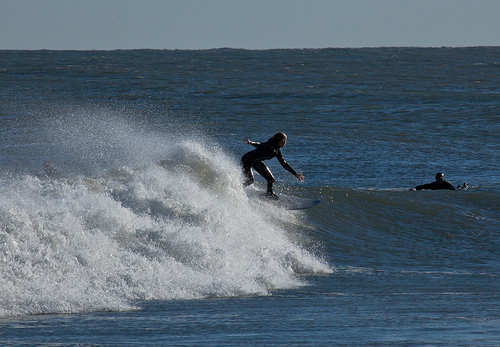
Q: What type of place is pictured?
A: It is an ocean.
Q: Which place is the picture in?
A: It is at the ocean.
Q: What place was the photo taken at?
A: It was taken at the ocean.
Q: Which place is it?
A: It is an ocean.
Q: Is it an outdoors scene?
A: Yes, it is outdoors.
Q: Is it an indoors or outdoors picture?
A: It is outdoors.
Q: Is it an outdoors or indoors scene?
A: It is outdoors.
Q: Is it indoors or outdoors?
A: It is outdoors.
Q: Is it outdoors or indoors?
A: It is outdoors.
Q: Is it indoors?
A: No, it is outdoors.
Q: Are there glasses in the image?
A: No, there are no glasses.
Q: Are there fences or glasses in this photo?
A: No, there are no glasses or fences.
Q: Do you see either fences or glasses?
A: No, there are no glasses or fences.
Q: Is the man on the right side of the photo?
A: Yes, the man is on the right of the image.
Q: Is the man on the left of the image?
A: No, the man is on the right of the image.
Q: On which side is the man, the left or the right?
A: The man is on the right of the image.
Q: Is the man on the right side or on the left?
A: The man is on the right of the image.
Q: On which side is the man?
A: The man is on the right of the image.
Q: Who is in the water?
A: The man is in the water.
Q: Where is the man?
A: The man is in the water.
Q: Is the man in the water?
A: Yes, the man is in the water.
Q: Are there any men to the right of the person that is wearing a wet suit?
A: Yes, there is a man to the right of the person.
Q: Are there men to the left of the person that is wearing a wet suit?
A: No, the man is to the right of the person.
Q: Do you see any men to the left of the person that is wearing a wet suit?
A: No, the man is to the right of the person.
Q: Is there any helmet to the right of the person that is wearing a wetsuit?
A: No, there is a man to the right of the person.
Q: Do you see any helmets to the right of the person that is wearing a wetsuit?
A: No, there is a man to the right of the person.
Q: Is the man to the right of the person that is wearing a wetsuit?
A: Yes, the man is to the right of the person.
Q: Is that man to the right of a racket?
A: No, the man is to the right of the person.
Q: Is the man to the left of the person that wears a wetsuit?
A: No, the man is to the right of the person.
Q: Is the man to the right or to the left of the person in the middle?
A: The man is to the right of the person.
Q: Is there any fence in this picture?
A: No, there are no fences.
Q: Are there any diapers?
A: No, there are no diapers.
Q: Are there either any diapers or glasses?
A: No, there are no diapers or glasses.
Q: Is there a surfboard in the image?
A: Yes, there is a surfboard.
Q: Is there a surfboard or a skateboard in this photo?
A: Yes, there is a surfboard.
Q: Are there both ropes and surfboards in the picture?
A: No, there is a surfboard but no ropes.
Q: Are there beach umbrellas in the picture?
A: No, there are no beach umbrellas.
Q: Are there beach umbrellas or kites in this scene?
A: No, there are no beach umbrellas or kites.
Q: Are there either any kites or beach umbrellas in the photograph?
A: No, there are no beach umbrellas or kites.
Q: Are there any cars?
A: No, there are no cars.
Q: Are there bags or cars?
A: No, there are no cars or bags.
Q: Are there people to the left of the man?
A: Yes, there is a person to the left of the man.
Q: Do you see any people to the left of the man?
A: Yes, there is a person to the left of the man.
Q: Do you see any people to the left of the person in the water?
A: Yes, there is a person to the left of the man.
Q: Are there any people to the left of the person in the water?
A: Yes, there is a person to the left of the man.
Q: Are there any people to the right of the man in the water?
A: No, the person is to the left of the man.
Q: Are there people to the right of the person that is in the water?
A: No, the person is to the left of the man.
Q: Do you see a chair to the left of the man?
A: No, there is a person to the left of the man.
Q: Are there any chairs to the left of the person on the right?
A: No, there is a person to the left of the man.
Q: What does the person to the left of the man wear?
A: The person wears a wetsuit.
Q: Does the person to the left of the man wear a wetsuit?
A: Yes, the person wears a wetsuit.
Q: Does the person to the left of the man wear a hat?
A: No, the person wears a wetsuit.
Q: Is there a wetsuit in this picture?
A: Yes, there is a wetsuit.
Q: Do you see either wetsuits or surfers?
A: Yes, there is a wetsuit.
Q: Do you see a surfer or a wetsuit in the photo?
A: Yes, there is a wetsuit.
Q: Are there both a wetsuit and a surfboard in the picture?
A: Yes, there are both a wetsuit and a surfboard.